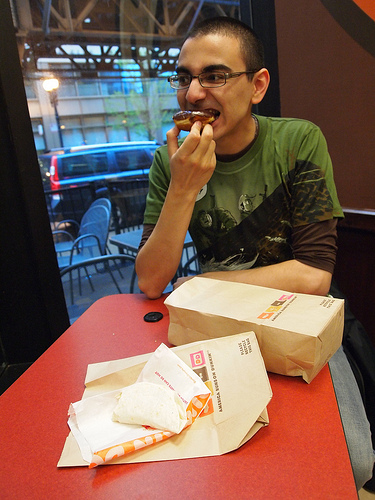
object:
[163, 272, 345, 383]
bag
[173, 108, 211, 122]
chocolate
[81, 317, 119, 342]
red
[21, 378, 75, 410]
top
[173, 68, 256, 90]
pair of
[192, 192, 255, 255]
design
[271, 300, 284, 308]
brown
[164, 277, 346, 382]
paper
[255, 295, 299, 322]
design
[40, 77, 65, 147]
street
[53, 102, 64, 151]
pole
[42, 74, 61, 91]
light on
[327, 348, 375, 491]
pants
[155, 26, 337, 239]
on man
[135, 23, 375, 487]
boy is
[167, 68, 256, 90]
glasses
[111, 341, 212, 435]
napkins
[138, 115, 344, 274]
boys shirt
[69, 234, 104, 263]
arm handle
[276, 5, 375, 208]
wall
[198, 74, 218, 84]
black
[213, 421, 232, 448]
flat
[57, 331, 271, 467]
bag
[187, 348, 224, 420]
duncan donut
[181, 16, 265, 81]
hair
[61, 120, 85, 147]
through window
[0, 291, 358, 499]
table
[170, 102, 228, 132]
eating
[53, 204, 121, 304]
chairs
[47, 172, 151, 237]
street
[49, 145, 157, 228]
car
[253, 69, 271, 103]
left ear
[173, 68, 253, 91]
wearing glasses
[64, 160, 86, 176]
windows